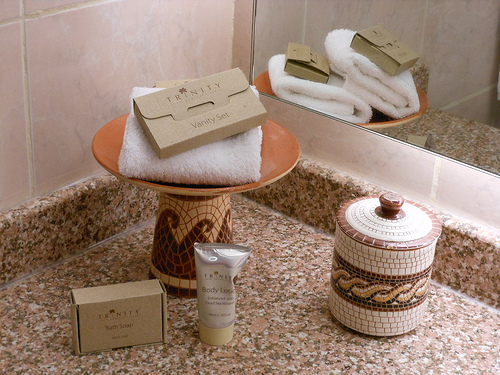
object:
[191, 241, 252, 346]
tube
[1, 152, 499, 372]
counter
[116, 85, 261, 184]
towel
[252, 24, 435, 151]
reflection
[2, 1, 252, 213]
wall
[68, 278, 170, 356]
box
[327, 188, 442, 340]
container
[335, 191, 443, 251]
cover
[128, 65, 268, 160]
box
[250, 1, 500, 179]
mirror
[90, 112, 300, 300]
stand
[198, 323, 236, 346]
cap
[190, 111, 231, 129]
vanity set